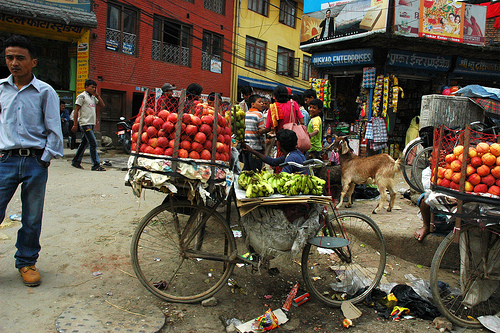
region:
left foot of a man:
[27, 270, 34, 287]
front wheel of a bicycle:
[318, 300, 330, 307]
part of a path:
[91, 222, 102, 245]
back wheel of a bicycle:
[186, 291, 198, 301]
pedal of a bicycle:
[272, 266, 279, 276]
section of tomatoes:
[191, 114, 202, 126]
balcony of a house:
[166, 46, 175, 53]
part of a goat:
[378, 169, 389, 172]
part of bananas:
[266, 187, 291, 189]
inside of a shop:
[349, 91, 390, 138]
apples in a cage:
[130, 79, 242, 194]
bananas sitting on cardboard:
[234, 164, 352, 206]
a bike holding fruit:
[120, 136, 392, 314]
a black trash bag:
[373, 283, 452, 323]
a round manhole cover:
[57, 292, 159, 332]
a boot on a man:
[16, 262, 45, 289]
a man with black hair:
[0, 35, 70, 291]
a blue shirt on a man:
[0, 70, 71, 149]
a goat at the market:
[320, 130, 411, 212]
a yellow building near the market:
[233, 0, 331, 167]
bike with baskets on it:
[112, 76, 388, 322]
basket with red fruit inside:
[123, 91, 240, 188]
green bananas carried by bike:
[232, 145, 349, 207]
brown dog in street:
[311, 133, 421, 213]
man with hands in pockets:
[0, 54, 57, 295]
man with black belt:
[0, 48, 93, 238]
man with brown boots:
[1, 220, 86, 290]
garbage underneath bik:
[212, 229, 440, 328]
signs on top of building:
[292, 0, 479, 62]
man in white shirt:
[75, 73, 121, 191]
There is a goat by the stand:
[315, 121, 413, 210]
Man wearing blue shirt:
[0, 38, 51, 289]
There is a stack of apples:
[137, 85, 235, 181]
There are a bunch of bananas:
[232, 163, 330, 208]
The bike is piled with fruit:
[132, 89, 396, 316]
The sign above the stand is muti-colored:
[418, 1, 470, 47]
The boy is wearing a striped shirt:
[236, 94, 270, 159]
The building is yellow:
[238, 0, 326, 127]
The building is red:
[93, 3, 236, 124]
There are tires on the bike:
[122, 182, 397, 327]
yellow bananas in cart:
[246, 170, 328, 197]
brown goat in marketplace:
[329, 138, 421, 223]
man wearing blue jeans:
[3, 46, 48, 293]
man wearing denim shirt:
[3, 37, 80, 322]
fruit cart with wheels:
[128, 76, 373, 312]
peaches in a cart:
[142, 103, 224, 159]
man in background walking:
[71, 77, 110, 172]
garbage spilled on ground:
[356, 277, 430, 324]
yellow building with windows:
[238, 2, 310, 82]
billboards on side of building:
[395, 1, 482, 51]